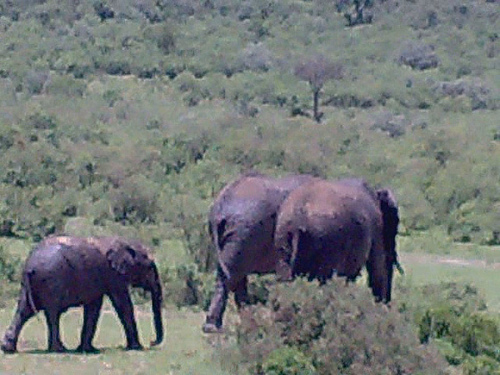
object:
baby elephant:
[2, 235, 163, 351]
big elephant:
[203, 175, 292, 333]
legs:
[34, 297, 156, 347]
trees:
[1, 3, 474, 250]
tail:
[207, 216, 234, 281]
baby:
[1, 228, 167, 360]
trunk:
[144, 280, 165, 347]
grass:
[4, 2, 496, 373]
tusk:
[390, 249, 405, 283]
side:
[265, 183, 294, 273]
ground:
[6, 2, 498, 367]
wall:
[191, 143, 315, 183]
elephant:
[191, 159, 411, 345]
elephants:
[1, 169, 401, 351]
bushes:
[0, 0, 500, 375]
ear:
[99, 253, 134, 277]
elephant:
[28, 229, 183, 349]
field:
[0, 2, 498, 372]